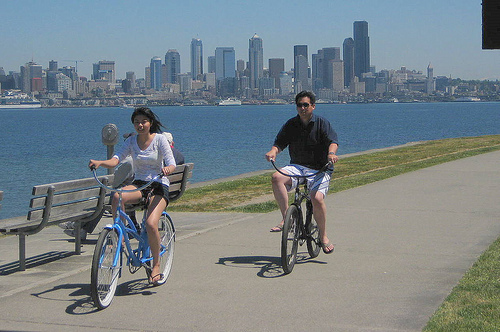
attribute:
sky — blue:
[4, 3, 496, 88]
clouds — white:
[197, 11, 251, 38]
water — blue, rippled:
[0, 95, 493, 215]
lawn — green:
[423, 245, 496, 330]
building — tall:
[340, 21, 374, 91]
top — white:
[123, 127, 172, 187]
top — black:
[270, 115, 337, 169]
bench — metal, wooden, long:
[3, 159, 195, 261]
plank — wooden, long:
[29, 163, 185, 193]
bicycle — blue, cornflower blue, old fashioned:
[88, 166, 175, 308]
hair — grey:
[162, 130, 174, 141]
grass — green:
[180, 133, 498, 206]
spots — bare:
[180, 185, 289, 212]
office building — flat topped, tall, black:
[349, 19, 369, 77]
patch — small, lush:
[449, 240, 487, 315]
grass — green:
[425, 234, 498, 327]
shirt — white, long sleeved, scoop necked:
[118, 136, 175, 187]